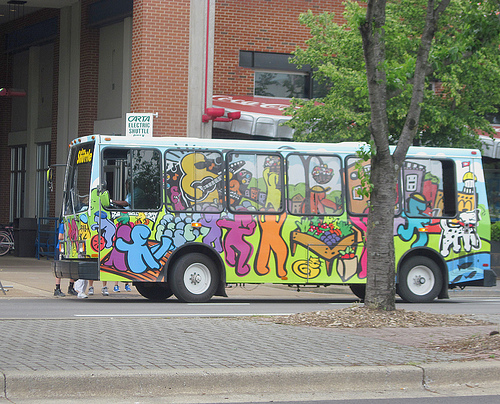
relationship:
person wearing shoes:
[44, 261, 85, 301] [39, 272, 87, 313]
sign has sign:
[123, 110, 153, 137] [123, 110, 153, 137]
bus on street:
[52, 132, 499, 294] [0, 291, 499, 402]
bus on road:
[52, 132, 499, 294] [0, 297, 499, 402]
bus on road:
[52, 134, 498, 303] [0, 297, 499, 402]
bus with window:
[52, 134, 498, 303] [162, 149, 228, 214]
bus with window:
[52, 134, 498, 303] [287, 147, 344, 218]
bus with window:
[52, 134, 498, 303] [223, 149, 282, 211]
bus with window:
[52, 134, 498, 303] [400, 155, 456, 217]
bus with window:
[52, 134, 498, 303] [345, 153, 401, 218]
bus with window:
[52, 132, 499, 294] [99, 147, 166, 211]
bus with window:
[52, 132, 499, 294] [163, 147, 224, 210]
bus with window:
[52, 132, 499, 294] [225, 152, 283, 208]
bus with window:
[52, 132, 499, 294] [62, 139, 95, 211]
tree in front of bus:
[339, 10, 477, 315] [56, 115, 497, 294]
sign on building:
[123, 110, 153, 137] [95, 0, 315, 144]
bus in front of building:
[52, 132, 499, 294] [4, 2, 499, 262]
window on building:
[247, 67, 334, 104] [0, 1, 485, 291]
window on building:
[234, 45, 321, 74] [0, 1, 485, 291]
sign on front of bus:
[123, 110, 153, 137] [54, 130, 499, 268]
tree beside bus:
[288, 0, 500, 316] [38, 122, 497, 301]